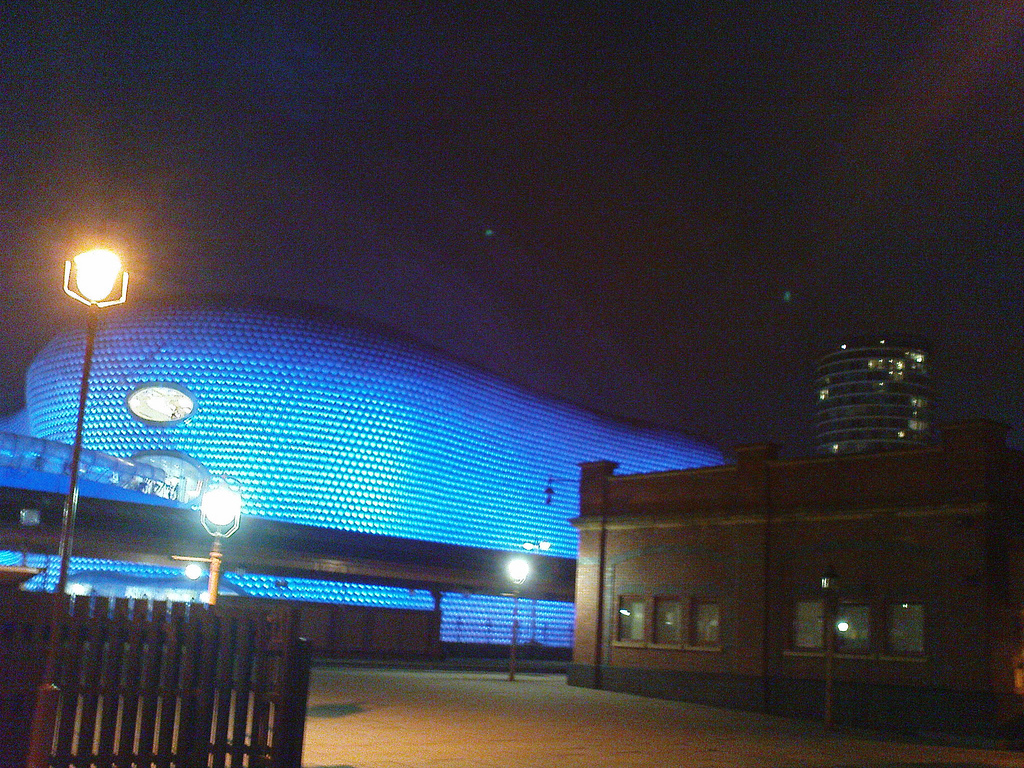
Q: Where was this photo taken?
A: On the street.